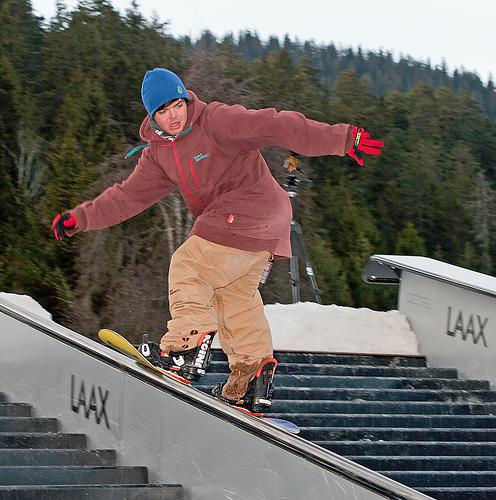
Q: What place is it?
A: It is a forest.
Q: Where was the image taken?
A: It was taken at the forest.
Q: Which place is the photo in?
A: It is at the forest.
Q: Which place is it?
A: It is a forest.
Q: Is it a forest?
A: Yes, it is a forest.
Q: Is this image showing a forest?
A: Yes, it is showing a forest.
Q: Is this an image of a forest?
A: Yes, it is showing a forest.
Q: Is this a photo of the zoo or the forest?
A: It is showing the forest.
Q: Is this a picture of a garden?
A: No, the picture is showing a forest.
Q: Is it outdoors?
A: Yes, it is outdoors.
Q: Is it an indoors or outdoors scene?
A: It is outdoors.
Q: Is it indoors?
A: No, it is outdoors.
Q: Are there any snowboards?
A: Yes, there is a snowboard.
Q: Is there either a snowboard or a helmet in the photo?
A: Yes, there is a snowboard.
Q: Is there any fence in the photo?
A: No, there are no fences.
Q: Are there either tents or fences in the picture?
A: No, there are no fences or tents.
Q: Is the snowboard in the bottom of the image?
A: Yes, the snowboard is in the bottom of the image.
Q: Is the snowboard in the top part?
A: No, the snowboard is in the bottom of the image.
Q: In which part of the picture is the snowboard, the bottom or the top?
A: The snowboard is in the bottom of the image.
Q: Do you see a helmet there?
A: No, there are no helmets.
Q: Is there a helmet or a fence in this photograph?
A: No, there are no helmets or fences.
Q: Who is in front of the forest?
A: The boy is in front of the forest.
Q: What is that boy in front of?
A: The boy is in front of the forest.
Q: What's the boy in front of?
A: The boy is in front of the forest.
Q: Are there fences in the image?
A: No, there are no fences.